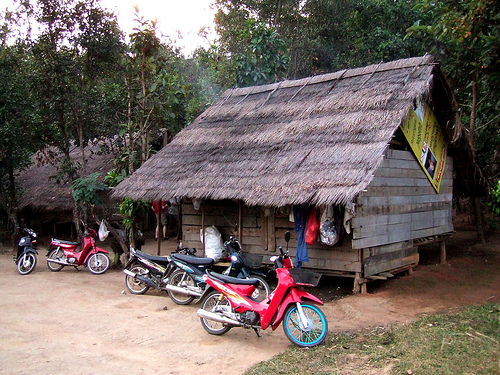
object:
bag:
[200, 224, 228, 263]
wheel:
[281, 303, 329, 348]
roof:
[106, 52, 442, 210]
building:
[0, 51, 499, 297]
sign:
[397, 98, 450, 195]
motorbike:
[194, 230, 329, 347]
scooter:
[161, 223, 271, 305]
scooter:
[122, 239, 197, 296]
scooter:
[45, 226, 112, 275]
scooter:
[13, 228, 40, 276]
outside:
[0, 182, 500, 375]